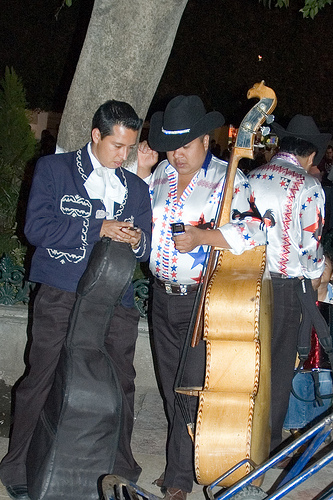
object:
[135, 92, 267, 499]
man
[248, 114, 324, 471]
man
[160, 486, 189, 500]
shoe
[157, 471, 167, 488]
shoe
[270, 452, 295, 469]
shoe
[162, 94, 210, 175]
head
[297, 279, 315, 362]
strap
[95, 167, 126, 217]
tie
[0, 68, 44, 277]
tree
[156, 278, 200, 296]
belt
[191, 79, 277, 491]
cello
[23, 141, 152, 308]
shirt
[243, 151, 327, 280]
shirt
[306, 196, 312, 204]
star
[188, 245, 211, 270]
star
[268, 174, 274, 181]
star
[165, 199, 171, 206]
star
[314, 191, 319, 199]
star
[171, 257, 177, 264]
star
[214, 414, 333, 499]
pipe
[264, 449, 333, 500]
pole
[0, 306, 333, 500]
ground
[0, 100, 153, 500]
man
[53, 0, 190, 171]
tree trunk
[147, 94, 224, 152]
black hat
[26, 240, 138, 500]
case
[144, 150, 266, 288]
shirt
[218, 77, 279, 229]
handle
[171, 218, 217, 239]
paint